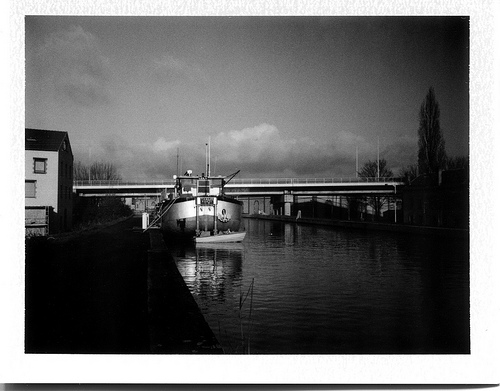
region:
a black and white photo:
[23, 12, 473, 356]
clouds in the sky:
[240, 124, 337, 177]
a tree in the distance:
[414, 84, 454, 190]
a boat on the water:
[171, 147, 246, 246]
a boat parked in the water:
[166, 142, 245, 244]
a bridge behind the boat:
[240, 175, 405, 195]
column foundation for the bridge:
[283, 195, 293, 217]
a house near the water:
[25, 124, 76, 234]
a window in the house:
[33, 159, 44, 171]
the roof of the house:
[24, 125, 75, 147]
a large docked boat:
[154, 138, 241, 233]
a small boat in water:
[191, 224, 246, 246]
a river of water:
[132, 193, 464, 348]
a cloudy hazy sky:
[26, 16, 468, 184]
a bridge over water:
[71, 178, 405, 220]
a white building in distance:
[22, 128, 74, 231]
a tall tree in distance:
[419, 84, 446, 185]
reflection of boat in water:
[169, 248, 242, 309]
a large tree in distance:
[357, 159, 391, 179]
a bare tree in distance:
[89, 161, 121, 181]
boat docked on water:
[151, 162, 231, 254]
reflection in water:
[180, 255, 234, 298]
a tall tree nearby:
[406, 82, 443, 184]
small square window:
[32, 153, 56, 180]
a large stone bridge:
[80, 178, 400, 193]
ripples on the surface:
[280, 250, 371, 305]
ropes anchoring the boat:
[154, 203, 169, 225]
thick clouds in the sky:
[156, 133, 399, 178]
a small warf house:
[19, 120, 66, 229]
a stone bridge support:
[284, 195, 296, 222]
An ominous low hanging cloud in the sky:
[164, 122, 364, 174]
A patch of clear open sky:
[217, 42, 312, 107]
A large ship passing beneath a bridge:
[152, 161, 250, 248]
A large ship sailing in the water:
[156, 157, 245, 239]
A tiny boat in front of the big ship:
[192, 221, 252, 249]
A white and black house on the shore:
[22, 123, 92, 238]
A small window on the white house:
[31, 155, 52, 180]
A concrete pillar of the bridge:
[281, 191, 294, 222]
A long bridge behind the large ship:
[72, 177, 406, 202]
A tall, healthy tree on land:
[411, 85, 456, 192]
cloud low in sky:
[98, 123, 433, 179]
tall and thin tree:
[416, 85, 446, 177]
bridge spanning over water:
[71, 175, 408, 243]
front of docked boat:
[147, 174, 243, 236]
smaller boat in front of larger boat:
[164, 198, 249, 246]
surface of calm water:
[163, 218, 472, 356]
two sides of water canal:
[145, 208, 477, 353]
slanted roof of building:
[27, 129, 68, 151]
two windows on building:
[25, 150, 56, 207]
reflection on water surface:
[174, 238, 242, 300]